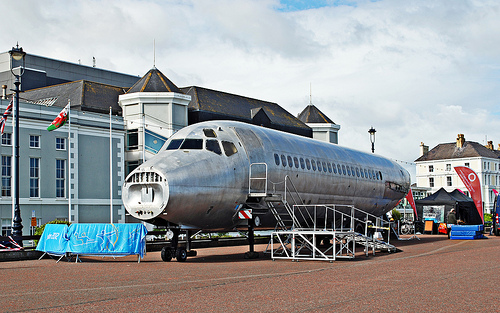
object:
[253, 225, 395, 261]
ramp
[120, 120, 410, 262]
airplane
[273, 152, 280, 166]
window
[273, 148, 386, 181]
row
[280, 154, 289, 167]
window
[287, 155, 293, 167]
window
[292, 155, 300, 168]
window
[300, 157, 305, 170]
window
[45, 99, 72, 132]
flag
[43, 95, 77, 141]
wind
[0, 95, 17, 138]
union jack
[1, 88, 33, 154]
wind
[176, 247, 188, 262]
wheel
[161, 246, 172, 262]
wheel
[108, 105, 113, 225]
pole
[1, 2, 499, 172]
day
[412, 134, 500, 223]
building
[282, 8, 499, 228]
background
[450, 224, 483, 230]
box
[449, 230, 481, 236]
box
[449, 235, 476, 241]
box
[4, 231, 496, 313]
ground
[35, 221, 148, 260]
sign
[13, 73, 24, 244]
pole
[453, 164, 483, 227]
sign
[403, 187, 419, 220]
sign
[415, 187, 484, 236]
tent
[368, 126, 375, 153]
light post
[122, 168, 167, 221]
propeller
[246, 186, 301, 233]
steps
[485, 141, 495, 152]
chimney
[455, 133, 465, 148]
chimney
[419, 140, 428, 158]
chimney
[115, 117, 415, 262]
display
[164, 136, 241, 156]
cockpit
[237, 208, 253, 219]
sign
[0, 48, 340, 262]
building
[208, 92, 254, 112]
grey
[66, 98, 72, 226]
pole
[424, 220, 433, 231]
sign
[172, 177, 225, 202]
part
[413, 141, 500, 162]
roof